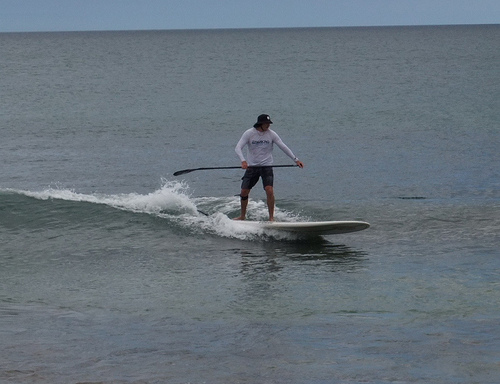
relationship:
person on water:
[221, 110, 307, 219] [0, 30, 499, 383]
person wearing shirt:
[221, 110, 307, 219] [232, 126, 296, 177]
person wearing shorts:
[221, 110, 307, 219] [235, 165, 282, 193]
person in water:
[221, 110, 307, 219] [0, 30, 499, 383]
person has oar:
[221, 110, 307, 219] [171, 159, 310, 182]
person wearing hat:
[221, 110, 307, 219] [251, 110, 276, 127]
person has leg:
[221, 110, 307, 219] [228, 165, 263, 223]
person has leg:
[221, 110, 307, 219] [257, 162, 282, 224]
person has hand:
[221, 110, 307, 219] [239, 158, 250, 173]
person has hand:
[221, 110, 307, 219] [293, 154, 304, 175]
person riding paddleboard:
[221, 110, 307, 219] [213, 206, 382, 245]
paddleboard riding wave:
[213, 206, 382, 245] [78, 179, 282, 244]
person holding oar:
[221, 110, 307, 219] [171, 159, 310, 182]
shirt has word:
[232, 126, 296, 177] [248, 137, 272, 149]